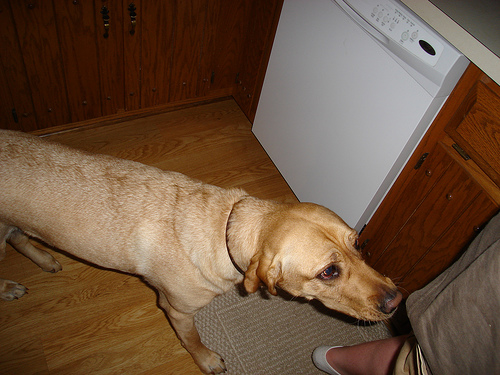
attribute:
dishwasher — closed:
[205, 3, 462, 203]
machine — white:
[272, 4, 462, 228]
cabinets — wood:
[2, 0, 277, 123]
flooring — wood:
[0, 93, 303, 373]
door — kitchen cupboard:
[0, 2, 302, 135]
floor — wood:
[0, 96, 297, 373]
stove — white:
[231, 0, 479, 246]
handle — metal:
[100, 5, 110, 37]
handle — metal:
[126, 2, 138, 35]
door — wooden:
[2, 1, 119, 131]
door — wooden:
[121, 0, 216, 110]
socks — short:
[309, 335, 353, 368]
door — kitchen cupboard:
[120, 2, 255, 116]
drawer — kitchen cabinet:
[438, 75, 499, 189]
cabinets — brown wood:
[46, 10, 223, 97]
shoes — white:
[259, 326, 361, 373]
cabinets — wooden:
[1, 1, 247, 140]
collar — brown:
[224, 192, 245, 273]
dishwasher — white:
[247, 0, 471, 239]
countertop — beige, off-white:
[399, 0, 499, 90]